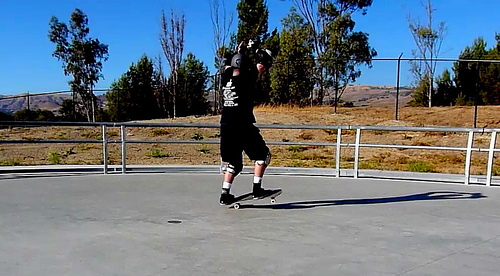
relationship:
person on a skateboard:
[219, 36, 274, 203] [222, 186, 279, 209]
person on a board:
[219, 36, 274, 203] [220, 192, 289, 208]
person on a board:
[219, 36, 274, 203] [224, 190, 286, 213]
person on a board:
[219, 36, 274, 203] [227, 193, 282, 210]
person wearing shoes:
[214, 37, 278, 202] [216, 183, 270, 206]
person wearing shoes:
[219, 36, 274, 203] [220, 182, 267, 204]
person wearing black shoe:
[219, 36, 274, 203] [220, 188, 235, 205]